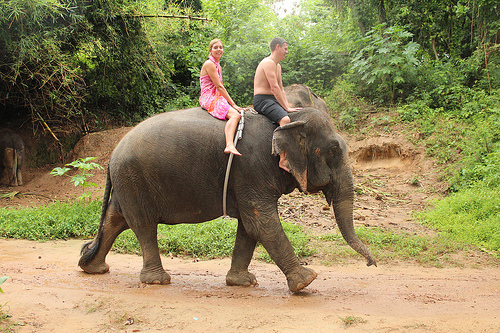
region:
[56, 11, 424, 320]
A man and woman riding an elephant.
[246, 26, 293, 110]
Man with no shirt on.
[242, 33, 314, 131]
Man wearing a pair of black shorts.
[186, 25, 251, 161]
A woman wearing pink dress.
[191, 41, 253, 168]
Woman has no shoes on.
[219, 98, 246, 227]
A rope around an elephant.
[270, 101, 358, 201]
An elephant's head.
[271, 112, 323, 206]
An elephant's right ear.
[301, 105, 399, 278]
An elephant's trunk.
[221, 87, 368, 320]
An elephant's front legs.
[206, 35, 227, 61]
the head of a woman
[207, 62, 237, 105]
the arm of a woman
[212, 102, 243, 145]
the leg of a woman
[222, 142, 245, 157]
the foot of a woman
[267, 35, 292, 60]
the head of a man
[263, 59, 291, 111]
the arm of a man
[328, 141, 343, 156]
the eye of an elephant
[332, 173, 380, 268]
the trunk of an elephant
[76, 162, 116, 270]
the tail of an elephant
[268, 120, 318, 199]
the ear of an elephant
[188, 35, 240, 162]
woman in pink dress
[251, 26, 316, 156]
man in black shorts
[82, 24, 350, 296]
couple riding on elephant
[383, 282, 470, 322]
ground covered in mud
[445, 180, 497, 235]
grass growing beside dirt path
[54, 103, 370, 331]
large grey elephant walking on path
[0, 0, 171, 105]
thick trees with green leaves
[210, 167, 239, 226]
brown harness around elephant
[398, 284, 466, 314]
elephant tracks in mud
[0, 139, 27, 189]
brown stump beside path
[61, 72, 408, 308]
this is an elephant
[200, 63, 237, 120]
this is a dress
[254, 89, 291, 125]
these are black shorts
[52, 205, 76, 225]
this is green grass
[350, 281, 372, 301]
this is brown dirt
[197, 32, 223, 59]
this is blonde hair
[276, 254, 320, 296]
the front right foot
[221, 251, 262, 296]
the front left leg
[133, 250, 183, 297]
the back right foot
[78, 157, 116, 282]
the black elephant tail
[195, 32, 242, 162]
a woman sitting on an elephant.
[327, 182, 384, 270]
an elephant's trunk.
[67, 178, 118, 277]
a tail on an elephant.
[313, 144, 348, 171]
the right eye of an elephant.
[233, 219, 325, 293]
The right leg of an elephant.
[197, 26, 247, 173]
a woman riding an elephant.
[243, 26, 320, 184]
a man riding an elephant.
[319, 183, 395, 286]
a trunk on an elephant.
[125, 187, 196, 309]
a hind leg.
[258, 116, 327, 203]
elephant ear.